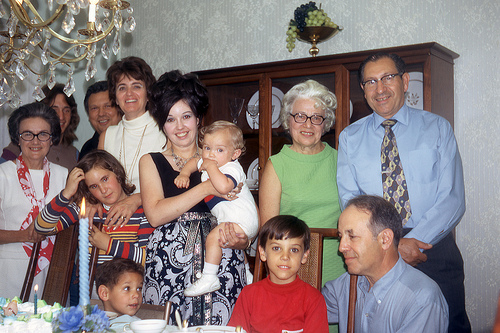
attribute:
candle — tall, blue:
[68, 188, 107, 329]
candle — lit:
[65, 196, 129, 297]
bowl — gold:
[293, 22, 340, 54]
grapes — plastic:
[305, 7, 338, 32]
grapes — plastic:
[291, 0, 316, 32]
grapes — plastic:
[281, 21, 298, 51]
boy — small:
[226, 215, 328, 329]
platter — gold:
[293, 26, 339, 57]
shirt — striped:
[246, 260, 330, 328]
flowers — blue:
[49, 300, 114, 330]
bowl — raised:
[294, 29, 339, 56]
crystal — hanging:
[121, 13, 134, 33]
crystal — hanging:
[97, 41, 111, 60]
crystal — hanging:
[83, 59, 91, 81]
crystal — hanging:
[59, 75, 75, 96]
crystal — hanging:
[15, 60, 27, 80]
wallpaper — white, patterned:
[121, 2, 496, 331]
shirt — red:
[224, 274, 329, 329]